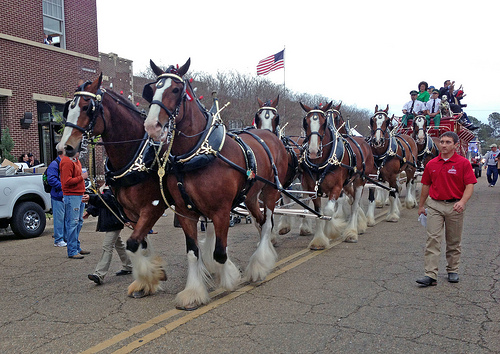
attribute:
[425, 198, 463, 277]
pants — grey, brown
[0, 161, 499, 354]
floor — grey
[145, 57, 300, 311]
horse — here, brown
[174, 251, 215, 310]
leg — white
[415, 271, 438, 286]
shoe — black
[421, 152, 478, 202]
shirt — red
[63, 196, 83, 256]
pants — blue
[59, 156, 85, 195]
sweater — red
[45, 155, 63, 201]
shirt — blue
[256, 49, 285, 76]
flag — american, here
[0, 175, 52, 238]
truck — white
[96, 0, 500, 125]
sky — here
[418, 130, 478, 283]
man — here, light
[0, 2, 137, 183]
wall — brick, here, brown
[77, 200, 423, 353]
line — yellow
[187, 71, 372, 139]
tree — here